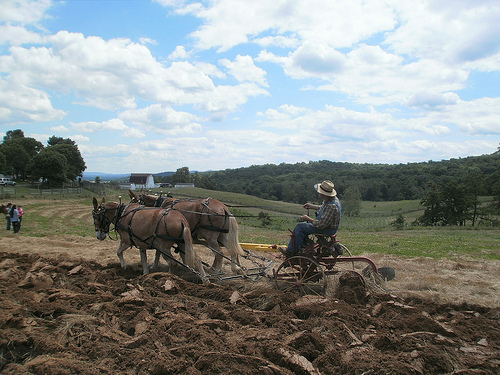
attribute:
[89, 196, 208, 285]
horse — brown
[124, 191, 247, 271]
horse — brown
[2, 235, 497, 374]
ground — brown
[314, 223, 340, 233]
belt — black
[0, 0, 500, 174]
sky — blue, fluffy, white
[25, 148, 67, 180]
tree — green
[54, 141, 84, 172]
tree — green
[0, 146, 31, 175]
tree — green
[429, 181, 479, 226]
tree — green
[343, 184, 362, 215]
tree — green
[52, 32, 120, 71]
cloud — white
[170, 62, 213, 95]
cloud — white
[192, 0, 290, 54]
cloud — white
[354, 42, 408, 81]
cloud — white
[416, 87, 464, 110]
cloud — white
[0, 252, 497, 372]
dirt — freshly ploughed, dark brown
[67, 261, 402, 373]
eart — dark, well-tilled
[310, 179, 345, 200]
hat — tan, brimmed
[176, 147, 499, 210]
hill — tree covered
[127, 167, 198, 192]
buildings — rolling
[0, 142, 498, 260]
hills — green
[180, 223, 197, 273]
tail — blonde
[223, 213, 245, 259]
tail — blonde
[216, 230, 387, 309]
plow — red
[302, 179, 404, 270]
shirt — plaid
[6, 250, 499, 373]
field — freshly plowed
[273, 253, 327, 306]
wheel — elderly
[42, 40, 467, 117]
clouds — fluffy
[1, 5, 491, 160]
sky — bright blue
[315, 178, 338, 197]
hat — straw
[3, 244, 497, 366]
earth — rich